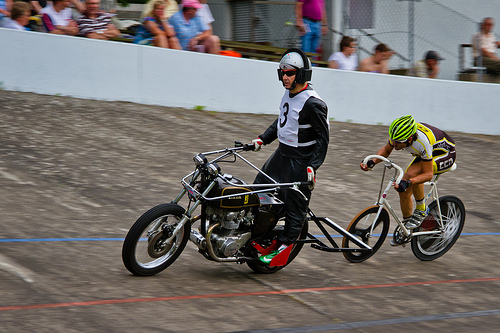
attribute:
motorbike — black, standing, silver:
[198, 171, 245, 232]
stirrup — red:
[279, 257, 284, 263]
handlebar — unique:
[259, 185, 293, 186]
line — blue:
[37, 235, 80, 245]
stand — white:
[143, 50, 209, 89]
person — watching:
[182, 2, 215, 22]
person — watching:
[88, 0, 102, 12]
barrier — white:
[387, 84, 443, 113]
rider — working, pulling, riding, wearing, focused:
[279, 54, 322, 170]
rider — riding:
[389, 117, 454, 196]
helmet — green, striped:
[399, 120, 410, 140]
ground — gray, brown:
[54, 147, 105, 189]